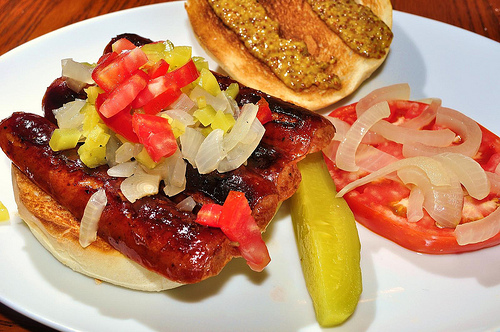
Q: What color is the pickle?
A: Green.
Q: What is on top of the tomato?
A: Onions.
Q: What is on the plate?
A: Food.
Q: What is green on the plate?
A: Pickle.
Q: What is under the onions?
A: Tomato.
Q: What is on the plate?
A: Food.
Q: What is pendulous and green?
A: A pickle slice.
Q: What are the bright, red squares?
A: Tomato bits.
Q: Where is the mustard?
A: On the bun, at the top of the plate.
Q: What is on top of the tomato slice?
A: Thin slices of onion.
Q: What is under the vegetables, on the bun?
A: Cooked meat.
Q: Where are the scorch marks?
A: On the top of the meat.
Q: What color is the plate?
A: White.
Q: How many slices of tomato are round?
A: One.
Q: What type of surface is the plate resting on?
A: Wood.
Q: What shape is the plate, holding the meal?
A: Oval.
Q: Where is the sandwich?
A: On plate.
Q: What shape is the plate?
A: Round.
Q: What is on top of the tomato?
A: Onions.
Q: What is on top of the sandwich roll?
A: Square piece of meat.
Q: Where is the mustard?
A: On top bun.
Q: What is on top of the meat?
A: Vegetable topping.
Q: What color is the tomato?
A: Red.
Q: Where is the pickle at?
A: By the tomato and sandwich.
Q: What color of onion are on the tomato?
A: White.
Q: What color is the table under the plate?
A: Brown.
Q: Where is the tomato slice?
A: Under the onions.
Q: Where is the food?
A: On a plate.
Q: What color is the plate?
A: White.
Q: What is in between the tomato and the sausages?
A: A pickle.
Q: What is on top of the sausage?
A: Onions, tomato, and peppers.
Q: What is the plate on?
A: A table.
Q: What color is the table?
A: Brown.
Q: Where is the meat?
A: On top of the bun.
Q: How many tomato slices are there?
A: One.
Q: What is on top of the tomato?
A: Onions.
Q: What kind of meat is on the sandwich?
A: A bratwurst.